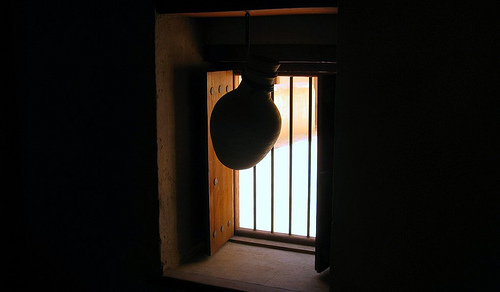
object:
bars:
[302, 75, 315, 239]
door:
[202, 68, 237, 259]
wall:
[380, 3, 500, 292]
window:
[228, 68, 319, 244]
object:
[209, 51, 286, 169]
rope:
[235, 16, 262, 57]